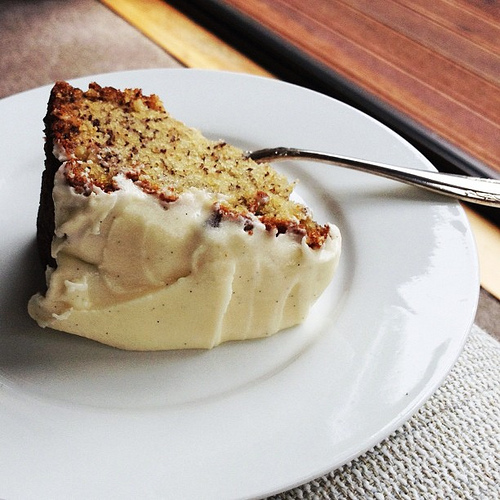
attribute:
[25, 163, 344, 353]
frosting — white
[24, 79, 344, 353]
food — sweet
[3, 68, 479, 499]
plate — white, ceramic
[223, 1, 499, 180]
floor — wood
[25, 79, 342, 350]
cake — slice, tasty, sweet, tempting, triangular, rough, irregular, yellow, brown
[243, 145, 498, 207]
utensil — shiny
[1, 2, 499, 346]
table — wooden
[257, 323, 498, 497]
mat — white, woven